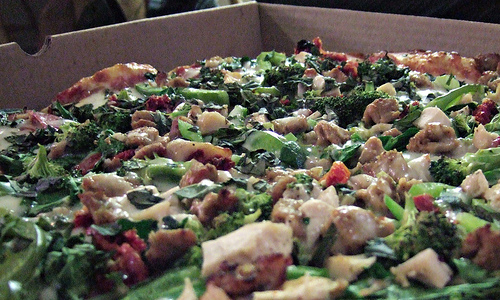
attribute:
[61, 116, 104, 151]
broccoli — green, dark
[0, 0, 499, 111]
cardboard box — brown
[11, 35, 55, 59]
half circle — half 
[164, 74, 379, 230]
surface — stripes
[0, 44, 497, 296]
toppings — heavy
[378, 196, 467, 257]
broccoli — green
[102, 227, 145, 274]
meat — reddish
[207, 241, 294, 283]
meat — reddish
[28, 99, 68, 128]
meat — reddish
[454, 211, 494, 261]
meat — reddish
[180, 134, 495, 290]
meat chunks — chunks , chicken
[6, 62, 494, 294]
dish — goopy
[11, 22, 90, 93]
notch — little, round, semicircle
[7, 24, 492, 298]
veggie food — green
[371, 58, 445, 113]
cheese — Yellow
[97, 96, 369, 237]
veggies — green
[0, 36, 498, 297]
pizza — gloppy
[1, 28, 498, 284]
food — curling up 